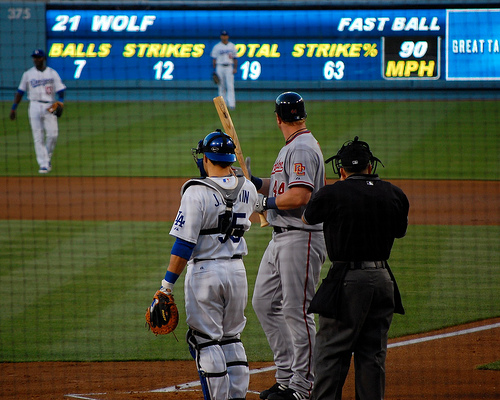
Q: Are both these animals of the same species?
A: No, they are wolves and bears.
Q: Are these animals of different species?
A: Yes, they are wolves and bears.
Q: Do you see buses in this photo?
A: No, there are no buses.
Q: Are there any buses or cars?
A: No, there are no buses or cars.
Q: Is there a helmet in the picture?
A: Yes, there is a helmet.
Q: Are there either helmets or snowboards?
A: Yes, there is a helmet.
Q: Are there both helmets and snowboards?
A: No, there is a helmet but no snowboards.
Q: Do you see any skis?
A: No, there are no skis.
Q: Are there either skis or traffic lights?
A: No, there are no skis or traffic lights.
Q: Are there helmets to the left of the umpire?
A: Yes, there is a helmet to the left of the umpire.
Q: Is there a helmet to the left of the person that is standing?
A: Yes, there is a helmet to the left of the umpire.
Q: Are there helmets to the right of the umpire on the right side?
A: No, the helmet is to the left of the umpire.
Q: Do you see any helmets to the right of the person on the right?
A: No, the helmet is to the left of the umpire.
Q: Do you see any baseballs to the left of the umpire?
A: No, there is a helmet to the left of the umpire.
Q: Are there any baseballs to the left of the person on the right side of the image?
A: No, there is a helmet to the left of the umpire.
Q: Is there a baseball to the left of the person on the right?
A: No, there is a helmet to the left of the umpire.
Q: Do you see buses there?
A: No, there are no buses.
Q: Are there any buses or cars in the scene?
A: No, there are no buses or cars.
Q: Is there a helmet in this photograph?
A: Yes, there is a helmet.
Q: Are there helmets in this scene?
A: Yes, there is a helmet.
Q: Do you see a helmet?
A: Yes, there is a helmet.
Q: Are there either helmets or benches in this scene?
A: Yes, there is a helmet.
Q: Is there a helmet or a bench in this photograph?
A: Yes, there is a helmet.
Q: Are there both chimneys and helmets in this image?
A: No, there is a helmet but no chimneys.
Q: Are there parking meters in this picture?
A: No, there are no parking meters.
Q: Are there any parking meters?
A: No, there are no parking meters.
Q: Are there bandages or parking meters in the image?
A: No, there are no parking meters or bandages.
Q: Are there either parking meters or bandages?
A: No, there are no parking meters or bandages.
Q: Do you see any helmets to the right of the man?
A: Yes, there is a helmet to the right of the man.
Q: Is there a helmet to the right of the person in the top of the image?
A: Yes, there is a helmet to the right of the man.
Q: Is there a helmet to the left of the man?
A: No, the helmet is to the right of the man.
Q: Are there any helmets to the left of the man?
A: No, the helmet is to the right of the man.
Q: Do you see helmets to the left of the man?
A: No, the helmet is to the right of the man.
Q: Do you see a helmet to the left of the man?
A: No, the helmet is to the right of the man.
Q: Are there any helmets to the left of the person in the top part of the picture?
A: No, the helmet is to the right of the man.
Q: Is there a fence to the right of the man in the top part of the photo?
A: No, there is a helmet to the right of the man.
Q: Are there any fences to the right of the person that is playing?
A: No, there is a helmet to the right of the man.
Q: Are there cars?
A: No, there are no cars.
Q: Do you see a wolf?
A: Yes, there is a wolf.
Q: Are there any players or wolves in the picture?
A: Yes, there is a wolf.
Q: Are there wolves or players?
A: Yes, there is a wolf.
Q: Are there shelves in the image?
A: No, there are no shelves.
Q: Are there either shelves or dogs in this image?
A: No, there are no shelves or dogs.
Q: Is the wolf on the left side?
A: Yes, the wolf is on the left of the image.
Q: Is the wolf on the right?
A: No, the wolf is on the left of the image.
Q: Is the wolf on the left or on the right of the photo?
A: The wolf is on the left of the image.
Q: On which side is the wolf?
A: The wolf is on the left of the image.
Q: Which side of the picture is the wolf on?
A: The wolf is on the left of the image.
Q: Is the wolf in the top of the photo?
A: Yes, the wolf is in the top of the image.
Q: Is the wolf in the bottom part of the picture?
A: No, the wolf is in the top of the image.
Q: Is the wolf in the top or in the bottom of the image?
A: The wolf is in the top of the image.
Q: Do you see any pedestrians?
A: No, there are no pedestrians.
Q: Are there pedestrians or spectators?
A: No, there are no pedestrians or spectators.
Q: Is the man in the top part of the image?
A: Yes, the man is in the top of the image.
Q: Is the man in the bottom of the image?
A: No, the man is in the top of the image.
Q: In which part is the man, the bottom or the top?
A: The man is in the top of the image.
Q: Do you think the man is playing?
A: Yes, the man is playing.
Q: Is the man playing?
A: Yes, the man is playing.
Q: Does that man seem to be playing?
A: Yes, the man is playing.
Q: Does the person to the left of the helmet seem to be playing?
A: Yes, the man is playing.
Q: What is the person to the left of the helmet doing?
A: The man is playing.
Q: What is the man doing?
A: The man is playing.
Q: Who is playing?
A: The man is playing.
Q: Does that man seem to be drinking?
A: No, the man is playing.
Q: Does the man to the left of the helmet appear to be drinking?
A: No, the man is playing.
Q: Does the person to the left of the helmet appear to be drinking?
A: No, the man is playing.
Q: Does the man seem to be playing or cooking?
A: The man is playing.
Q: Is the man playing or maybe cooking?
A: The man is playing.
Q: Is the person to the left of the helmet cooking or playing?
A: The man is playing.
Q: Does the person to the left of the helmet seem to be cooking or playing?
A: The man is playing.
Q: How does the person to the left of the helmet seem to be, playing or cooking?
A: The man is playing.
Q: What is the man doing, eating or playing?
A: The man is playing.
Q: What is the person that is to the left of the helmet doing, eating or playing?
A: The man is playing.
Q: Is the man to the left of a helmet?
A: Yes, the man is to the left of a helmet.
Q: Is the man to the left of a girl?
A: No, the man is to the left of a helmet.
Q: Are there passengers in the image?
A: No, there are no passengers.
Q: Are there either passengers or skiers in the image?
A: No, there are no passengers or skiers.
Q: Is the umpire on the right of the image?
A: Yes, the umpire is on the right of the image.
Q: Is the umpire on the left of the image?
A: No, the umpire is on the right of the image.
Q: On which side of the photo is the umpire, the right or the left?
A: The umpire is on the right of the image.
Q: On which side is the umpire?
A: The umpire is on the right of the image.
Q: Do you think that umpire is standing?
A: Yes, the umpire is standing.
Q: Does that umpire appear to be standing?
A: Yes, the umpire is standing.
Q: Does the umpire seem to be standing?
A: Yes, the umpire is standing.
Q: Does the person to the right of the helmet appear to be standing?
A: Yes, the umpire is standing.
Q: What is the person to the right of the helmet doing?
A: The umpire is standing.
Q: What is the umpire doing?
A: The umpire is standing.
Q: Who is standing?
A: The umpire is standing.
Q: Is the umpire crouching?
A: No, the umpire is standing.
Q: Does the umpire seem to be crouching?
A: No, the umpire is standing.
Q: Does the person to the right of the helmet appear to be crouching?
A: No, the umpire is standing.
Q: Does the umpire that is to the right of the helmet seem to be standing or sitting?
A: The umpire is standing.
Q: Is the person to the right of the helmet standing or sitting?
A: The umpire is standing.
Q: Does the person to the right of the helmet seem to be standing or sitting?
A: The umpire is standing.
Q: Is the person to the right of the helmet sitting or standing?
A: The umpire is standing.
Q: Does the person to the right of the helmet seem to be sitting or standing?
A: The umpire is standing.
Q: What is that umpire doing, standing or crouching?
A: The umpire is standing.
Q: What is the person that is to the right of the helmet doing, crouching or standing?
A: The umpire is standing.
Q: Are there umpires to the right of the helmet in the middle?
A: Yes, there is an umpire to the right of the helmet.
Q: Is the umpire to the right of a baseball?
A: No, the umpire is to the right of the helmet.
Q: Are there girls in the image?
A: No, there are no girls.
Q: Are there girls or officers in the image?
A: No, there are no girls or officers.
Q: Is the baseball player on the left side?
A: Yes, the player is on the left of the image.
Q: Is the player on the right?
A: No, the player is on the left of the image.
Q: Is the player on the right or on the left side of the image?
A: The player is on the left of the image.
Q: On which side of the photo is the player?
A: The player is on the left of the image.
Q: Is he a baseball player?
A: Yes, this is a baseball player.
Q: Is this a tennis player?
A: No, this is a baseball player.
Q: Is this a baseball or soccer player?
A: This is a baseball player.